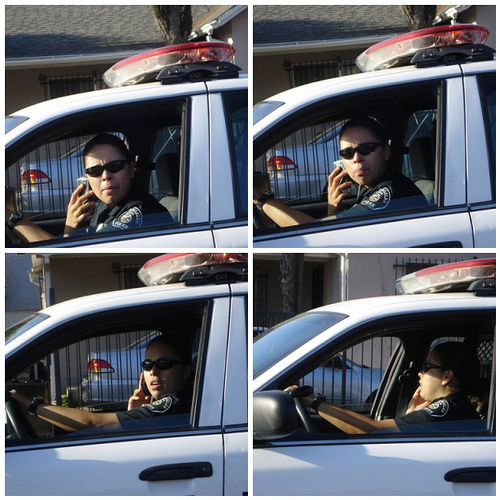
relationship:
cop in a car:
[6, 136, 179, 246] [6, 40, 248, 253]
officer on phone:
[255, 116, 429, 231] [336, 169, 350, 190]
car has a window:
[6, 40, 248, 253] [252, 81, 436, 234]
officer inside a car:
[255, 116, 429, 231] [6, 40, 248, 253]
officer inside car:
[255, 116, 429, 231] [6, 40, 248, 253]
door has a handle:
[256, 74, 473, 249] [412, 238, 462, 250]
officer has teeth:
[255, 116, 429, 231] [357, 168, 369, 178]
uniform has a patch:
[338, 176, 429, 220] [363, 185, 391, 211]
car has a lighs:
[6, 40, 248, 253] [354, 23, 487, 73]